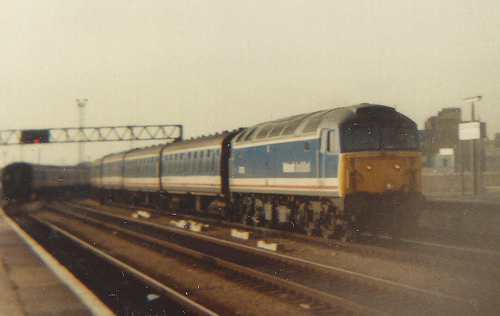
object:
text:
[280, 160, 309, 172]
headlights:
[360, 163, 374, 172]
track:
[109, 201, 499, 281]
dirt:
[23, 120, 498, 315]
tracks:
[42, 197, 482, 315]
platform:
[0, 210, 113, 315]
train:
[87, 102, 427, 243]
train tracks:
[21, 197, 380, 316]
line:
[0, 207, 117, 315]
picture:
[0, 0, 499, 315]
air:
[263, 21, 398, 70]